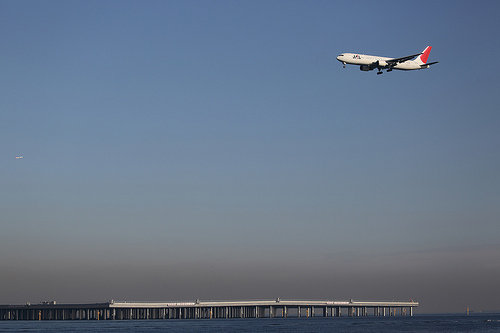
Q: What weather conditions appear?
A: It is clear.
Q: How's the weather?
A: It is clear.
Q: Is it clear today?
A: Yes, it is clear.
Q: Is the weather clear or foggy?
A: It is clear.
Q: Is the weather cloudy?
A: No, it is clear.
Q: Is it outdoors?
A: Yes, it is outdoors.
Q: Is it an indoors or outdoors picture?
A: It is outdoors.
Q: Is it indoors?
A: No, it is outdoors.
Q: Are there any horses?
A: No, there are no horses.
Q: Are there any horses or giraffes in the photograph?
A: No, there are no horses or giraffes.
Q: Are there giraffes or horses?
A: No, there are no horses or giraffes.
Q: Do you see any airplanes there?
A: Yes, there is an airplane.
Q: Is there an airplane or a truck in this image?
A: Yes, there is an airplane.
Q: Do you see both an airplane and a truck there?
A: No, there is an airplane but no trucks.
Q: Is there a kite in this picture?
A: No, there are no kites.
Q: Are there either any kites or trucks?
A: No, there are no kites or trucks.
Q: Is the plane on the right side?
A: Yes, the plane is on the right of the image.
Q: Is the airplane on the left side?
A: No, the airplane is on the right of the image.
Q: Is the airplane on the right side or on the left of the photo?
A: The airplane is on the right of the image.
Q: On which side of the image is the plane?
A: The plane is on the right of the image.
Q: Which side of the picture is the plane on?
A: The plane is on the right of the image.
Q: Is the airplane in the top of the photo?
A: Yes, the airplane is in the top of the image.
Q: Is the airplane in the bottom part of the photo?
A: No, the airplane is in the top of the image.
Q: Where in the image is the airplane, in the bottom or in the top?
A: The airplane is in the top of the image.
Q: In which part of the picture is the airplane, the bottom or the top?
A: The airplane is in the top of the image.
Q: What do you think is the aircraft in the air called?
A: The aircraft is an airplane.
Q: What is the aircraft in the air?
A: The aircraft is an airplane.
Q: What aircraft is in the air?
A: The aircraft is an airplane.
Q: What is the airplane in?
A: The airplane is in the air.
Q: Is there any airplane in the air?
A: Yes, there is an airplane in the air.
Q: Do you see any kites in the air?
A: No, there is an airplane in the air.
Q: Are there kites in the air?
A: No, there is an airplane in the air.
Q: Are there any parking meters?
A: No, there are no parking meters.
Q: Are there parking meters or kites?
A: No, there are no parking meters or kites.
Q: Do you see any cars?
A: No, there are no cars.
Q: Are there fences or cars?
A: No, there are no cars or fences.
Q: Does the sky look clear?
A: Yes, the sky is clear.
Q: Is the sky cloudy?
A: No, the sky is clear.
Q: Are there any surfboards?
A: No, there are no surfboards.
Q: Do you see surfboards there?
A: No, there are no surfboards.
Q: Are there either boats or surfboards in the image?
A: No, there are no surfboards or boats.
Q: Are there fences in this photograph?
A: No, there are no fences.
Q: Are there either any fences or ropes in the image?
A: No, there are no fences or ropes.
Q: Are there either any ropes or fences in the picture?
A: No, there are no fences or ropes.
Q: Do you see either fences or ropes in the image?
A: No, there are no fences or ropes.